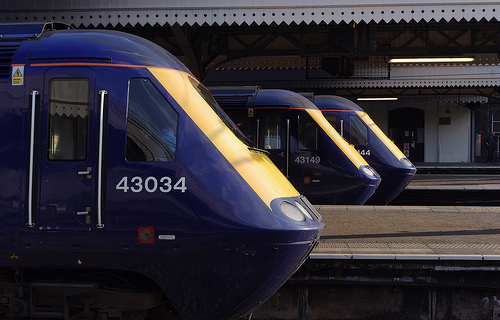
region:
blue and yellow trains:
[29, 55, 411, 301]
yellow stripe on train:
[165, 45, 288, 211]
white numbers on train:
[122, 163, 186, 210]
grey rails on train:
[0, 78, 114, 230]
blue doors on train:
[36, 70, 90, 220]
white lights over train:
[383, 44, 498, 89]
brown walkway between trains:
[326, 200, 483, 260]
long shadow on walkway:
[317, 213, 497, 247]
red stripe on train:
[24, 48, 149, 90]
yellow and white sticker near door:
[1, 62, 29, 92]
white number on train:
[115, 174, 131, 201]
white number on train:
[129, 174, 146, 211]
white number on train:
[145, 170, 160, 191]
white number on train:
[159, 172, 176, 198]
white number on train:
[292, 153, 294, 164]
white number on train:
[300, 156, 310, 171]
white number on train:
[305, 152, 317, 166]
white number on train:
[364, 149, 366, 157]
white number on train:
[367, 146, 373, 155]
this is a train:
[25, 30, 187, 317]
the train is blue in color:
[176, 205, 253, 265]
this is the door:
[41, 66, 94, 188]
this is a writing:
[110, 174, 200, 196]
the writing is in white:
[112, 168, 186, 195]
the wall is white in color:
[438, 128, 462, 153]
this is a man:
[479, 121, 495, 161]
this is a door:
[386, 104, 416, 138]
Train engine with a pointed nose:
[0, 16, 330, 319]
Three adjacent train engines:
[0, 29, 430, 317]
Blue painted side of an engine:
[1, 16, 327, 319]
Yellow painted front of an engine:
[148, 54, 305, 211]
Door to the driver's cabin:
[37, 62, 98, 233]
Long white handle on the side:
[93, 81, 111, 236]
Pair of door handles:
[73, 162, 98, 227]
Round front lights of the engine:
[267, 191, 324, 228]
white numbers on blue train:
[112, 174, 189, 196]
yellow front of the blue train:
[148, 58, 301, 215]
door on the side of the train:
[33, 66, 100, 231]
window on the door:
[45, 78, 86, 158]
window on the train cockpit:
[120, 76, 178, 168]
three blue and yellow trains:
[8, 17, 418, 319]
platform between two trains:
[289, 200, 498, 263]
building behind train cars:
[179, 33, 499, 155]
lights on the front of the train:
[270, 200, 311, 223]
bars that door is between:
[23, 89, 111, 227]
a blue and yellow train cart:
[0, 26, 367, 304]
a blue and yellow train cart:
[210, 72, 388, 187]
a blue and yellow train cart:
[326, 86, 448, 188]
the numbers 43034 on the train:
[111, 175, 199, 205]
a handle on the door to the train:
[88, 81, 116, 247]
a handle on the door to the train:
[24, 83, 41, 243]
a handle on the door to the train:
[279, 108, 299, 190]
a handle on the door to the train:
[250, 111, 266, 151]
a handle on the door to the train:
[335, 119, 349, 142]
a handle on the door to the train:
[82, 85, 135, 255]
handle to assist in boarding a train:
[24, 90, 39, 231]